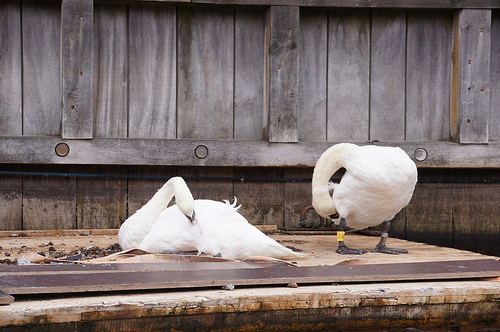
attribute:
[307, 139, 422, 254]
swan — in captivity, white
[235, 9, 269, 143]
plank — wooden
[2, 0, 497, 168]
fence — wooden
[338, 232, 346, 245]
tag — yellow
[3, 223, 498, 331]
platform — wooden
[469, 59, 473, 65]
nail — rusty